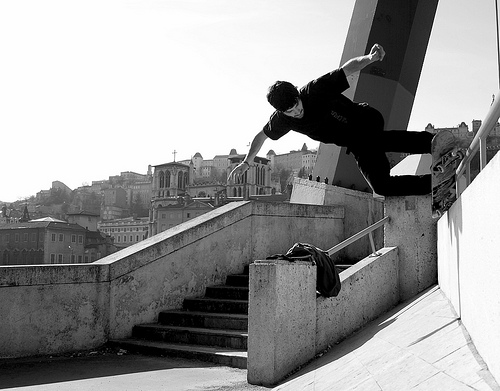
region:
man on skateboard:
[234, 39, 474, 267]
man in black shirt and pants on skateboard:
[248, 36, 488, 230]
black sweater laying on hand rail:
[232, 222, 386, 386]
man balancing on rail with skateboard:
[225, 33, 493, 226]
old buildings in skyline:
[5, 109, 222, 277]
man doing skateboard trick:
[232, 27, 483, 233]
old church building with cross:
[142, 134, 199, 210]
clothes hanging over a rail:
[281, 235, 345, 300]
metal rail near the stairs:
[305, 212, 392, 274]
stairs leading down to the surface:
[104, 247, 351, 373]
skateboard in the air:
[426, 128, 463, 222]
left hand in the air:
[311, 38, 386, 84]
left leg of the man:
[369, 128, 442, 155]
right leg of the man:
[359, 152, 436, 199]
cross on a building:
[172, 148, 178, 161]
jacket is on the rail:
[280, 235, 342, 308]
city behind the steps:
[30, 160, 298, 230]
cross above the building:
[170, 147, 180, 169]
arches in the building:
[157, 170, 189, 192]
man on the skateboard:
[268, 85, 452, 203]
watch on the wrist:
[238, 155, 253, 171]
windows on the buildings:
[107, 227, 157, 246]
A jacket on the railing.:
[266, 236, 360, 311]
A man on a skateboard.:
[220, 40, 475, 212]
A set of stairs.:
[123, 250, 290, 389]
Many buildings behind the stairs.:
[1, 148, 314, 262]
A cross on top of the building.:
[164, 143, 184, 170]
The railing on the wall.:
[446, 92, 498, 214]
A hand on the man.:
[368, 36, 394, 67]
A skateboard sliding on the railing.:
[423, 119, 478, 226]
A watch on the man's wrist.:
[242, 155, 252, 170]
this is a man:
[181, 11, 476, 229]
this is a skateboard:
[394, 97, 486, 256]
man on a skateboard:
[165, 62, 494, 277]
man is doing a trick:
[216, 37, 498, 263]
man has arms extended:
[165, 25, 415, 194]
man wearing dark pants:
[344, 105, 445, 214]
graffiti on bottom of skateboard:
[399, 127, 480, 240]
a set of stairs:
[115, 150, 390, 389]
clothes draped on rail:
[246, 208, 397, 379]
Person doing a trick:
[213, 31, 475, 241]